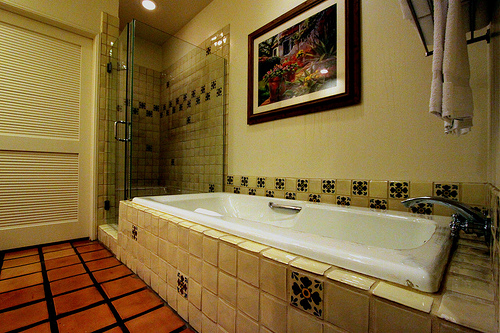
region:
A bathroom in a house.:
[0, 5, 493, 326]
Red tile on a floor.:
[0, 230, 190, 330]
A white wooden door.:
[0, 2, 95, 248]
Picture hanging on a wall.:
[240, 0, 364, 130]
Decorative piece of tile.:
[287, 268, 327, 322]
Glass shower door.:
[106, 19, 226, 230]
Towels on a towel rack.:
[429, 0, 474, 140]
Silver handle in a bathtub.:
[260, 198, 302, 217]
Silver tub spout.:
[400, 191, 492, 238]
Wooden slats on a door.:
[0, 20, 80, 227]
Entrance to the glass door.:
[113, 109, 135, 144]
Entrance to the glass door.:
[282, 266, 310, 317]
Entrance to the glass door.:
[103, 41, 114, 106]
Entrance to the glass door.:
[83, 161, 111, 215]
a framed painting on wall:
[244, 0, 364, 125]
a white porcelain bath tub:
[129, 190, 460, 295]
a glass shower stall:
[106, 20, 226, 234]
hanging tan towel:
[432, 2, 475, 137]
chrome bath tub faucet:
[400, 195, 491, 237]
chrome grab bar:
[267, 199, 301, 214]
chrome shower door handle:
[110, 116, 125, 138]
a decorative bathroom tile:
[285, 263, 322, 321]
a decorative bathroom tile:
[176, 268, 190, 298]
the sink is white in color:
[311, 220, 354, 243]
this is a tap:
[398, 187, 475, 224]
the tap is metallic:
[387, 195, 464, 225]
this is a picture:
[256, 27, 363, 103]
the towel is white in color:
[433, 34, 487, 81]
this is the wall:
[356, 23, 407, 115]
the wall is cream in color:
[358, 54, 414, 164]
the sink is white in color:
[324, 208, 375, 246]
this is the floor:
[1, 256, 129, 328]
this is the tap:
[394, 180, 479, 230]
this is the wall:
[368, 77, 410, 164]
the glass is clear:
[115, 36, 222, 136]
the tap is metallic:
[401, 186, 491, 228]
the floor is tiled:
[18, 247, 115, 322]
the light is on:
[142, 0, 156, 10]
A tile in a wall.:
[257, 255, 294, 297]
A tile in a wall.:
[197, 285, 223, 322]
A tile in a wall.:
[200, 257, 223, 295]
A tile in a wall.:
[185, 252, 205, 284]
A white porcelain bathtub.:
[92, 168, 498, 331]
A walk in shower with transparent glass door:
[94, 17, 240, 258]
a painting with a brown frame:
[243, 0, 369, 129]